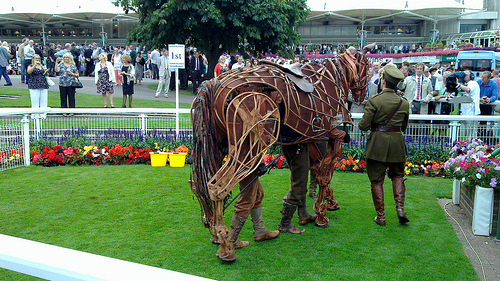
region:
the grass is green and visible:
[22, 136, 150, 238]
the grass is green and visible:
[90, 198, 165, 263]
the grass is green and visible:
[103, 147, 202, 265]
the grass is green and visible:
[60, 127, 220, 278]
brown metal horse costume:
[183, 46, 368, 253]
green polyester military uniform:
[366, 70, 411, 184]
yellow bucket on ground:
[148, 148, 166, 165]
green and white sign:
[169, 44, 184, 71]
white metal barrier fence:
[3, 108, 189, 164]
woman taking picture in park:
[27, 54, 51, 106]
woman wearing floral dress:
[97, 55, 116, 108]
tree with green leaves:
[118, 2, 306, 52]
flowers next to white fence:
[33, 144, 150, 167]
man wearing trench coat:
[408, 65, 433, 112]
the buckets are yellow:
[137, 137, 187, 172]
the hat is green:
[375, 62, 407, 85]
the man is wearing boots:
[355, 169, 422, 234]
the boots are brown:
[367, 177, 417, 228]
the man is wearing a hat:
[374, 62, 404, 87]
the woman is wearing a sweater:
[86, 47, 121, 95]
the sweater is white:
[87, 60, 123, 84]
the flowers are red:
[40, 146, 65, 166]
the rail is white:
[48, 98, 136, 130]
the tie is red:
[409, 73, 428, 103]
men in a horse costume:
[152, 30, 367, 260]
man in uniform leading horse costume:
[325, 40, 465, 233]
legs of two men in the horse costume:
[162, 82, 402, 261]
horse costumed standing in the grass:
[127, 20, 372, 269]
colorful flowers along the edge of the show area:
[24, 119, 498, 208]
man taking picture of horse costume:
[367, 22, 489, 124]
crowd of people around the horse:
[7, 10, 192, 118]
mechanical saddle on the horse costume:
[173, 45, 367, 265]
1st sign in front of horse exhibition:
[60, 15, 300, 259]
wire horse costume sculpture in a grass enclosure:
[171, 14, 366, 271]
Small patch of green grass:
[111, 202, 128, 227]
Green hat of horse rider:
[384, 65, 404, 79]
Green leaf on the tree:
[196, 12, 214, 25]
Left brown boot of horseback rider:
[370, 187, 388, 223]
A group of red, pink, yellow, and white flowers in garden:
[37, 147, 102, 169]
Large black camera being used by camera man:
[443, 71, 461, 90]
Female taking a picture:
[28, 53, 50, 108]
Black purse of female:
[69, 80, 86, 90]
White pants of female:
[24, 92, 49, 104]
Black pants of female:
[57, 90, 79, 106]